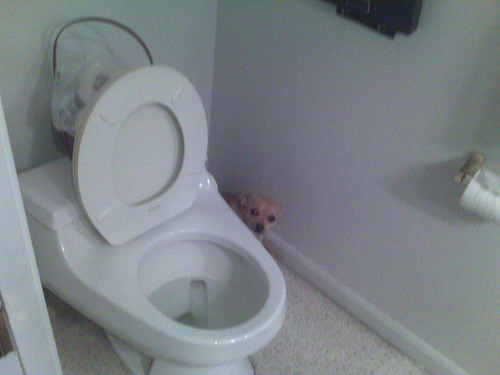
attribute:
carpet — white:
[50, 195, 429, 373]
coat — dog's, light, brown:
[215, 167, 269, 221]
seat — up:
[73, 66, 210, 247]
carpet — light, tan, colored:
[271, 290, 382, 374]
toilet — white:
[110, 213, 291, 373]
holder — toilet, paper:
[447, 147, 482, 199]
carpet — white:
[42, 238, 428, 373]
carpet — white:
[293, 321, 316, 336]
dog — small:
[230, 185, 292, 240]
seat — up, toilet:
[54, 48, 318, 357]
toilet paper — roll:
[43, 41, 144, 88]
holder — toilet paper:
[430, 120, 482, 190]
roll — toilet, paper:
[454, 162, 499, 226]